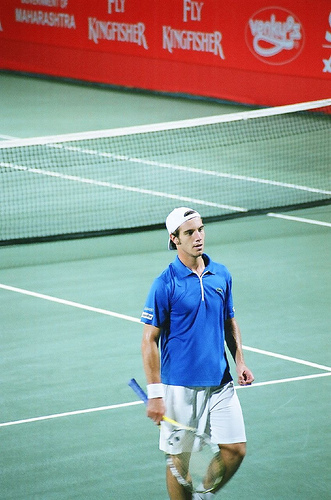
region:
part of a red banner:
[204, 76, 226, 90]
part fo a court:
[108, 438, 135, 472]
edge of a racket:
[214, 453, 225, 475]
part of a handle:
[132, 376, 147, 407]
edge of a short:
[232, 436, 243, 441]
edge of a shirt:
[198, 375, 220, 394]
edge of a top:
[181, 375, 222, 395]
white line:
[37, 375, 78, 444]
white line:
[27, 348, 96, 451]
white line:
[45, 361, 112, 471]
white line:
[52, 395, 124, 456]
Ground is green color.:
[17, 93, 229, 305]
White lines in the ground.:
[12, 119, 283, 446]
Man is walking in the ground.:
[128, 212, 256, 484]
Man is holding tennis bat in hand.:
[127, 376, 230, 493]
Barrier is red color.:
[7, 4, 301, 99]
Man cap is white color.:
[152, 198, 212, 255]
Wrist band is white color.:
[143, 376, 169, 407]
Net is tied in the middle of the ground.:
[9, 125, 287, 238]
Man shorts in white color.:
[135, 356, 252, 453]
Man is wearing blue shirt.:
[140, 266, 245, 381]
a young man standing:
[136, 200, 252, 493]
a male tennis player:
[130, 202, 251, 495]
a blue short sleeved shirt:
[138, 256, 238, 388]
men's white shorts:
[153, 379, 248, 454]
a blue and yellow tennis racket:
[119, 375, 222, 495]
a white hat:
[164, 205, 197, 255]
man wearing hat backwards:
[163, 205, 206, 261]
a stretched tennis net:
[0, 95, 329, 248]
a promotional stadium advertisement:
[13, 0, 72, 28]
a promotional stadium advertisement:
[242, 5, 307, 69]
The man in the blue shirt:
[127, 198, 259, 499]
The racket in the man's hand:
[125, 375, 226, 497]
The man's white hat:
[166, 204, 201, 254]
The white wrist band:
[144, 379, 167, 401]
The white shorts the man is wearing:
[153, 381, 249, 454]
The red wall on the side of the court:
[0, 0, 330, 115]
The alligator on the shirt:
[213, 284, 223, 295]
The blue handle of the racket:
[125, 375, 149, 407]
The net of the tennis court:
[0, 94, 330, 244]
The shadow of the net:
[1, 204, 329, 272]